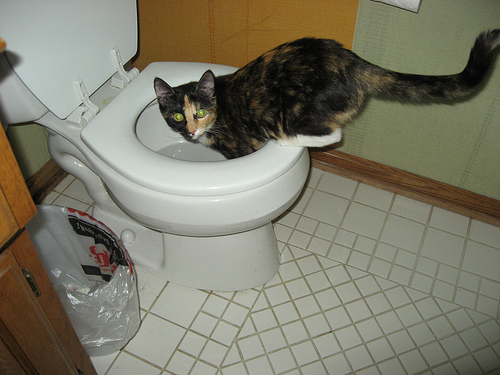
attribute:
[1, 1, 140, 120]
seat cover — toilet , white 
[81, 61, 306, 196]
seat — white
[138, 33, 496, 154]
cat — perched , calico , looking, black and brown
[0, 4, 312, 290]
toilet — white 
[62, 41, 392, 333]
toilet — white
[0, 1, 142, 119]
lid — open, white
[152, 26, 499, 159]
cat — black, tan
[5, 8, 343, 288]
toilet — porcelain , white 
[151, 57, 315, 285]
toilet — white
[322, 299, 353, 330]
tile — white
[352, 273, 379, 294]
tile — white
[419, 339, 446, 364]
tile — white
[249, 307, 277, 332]
tile — white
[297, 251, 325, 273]
tile — white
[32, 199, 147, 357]
trash can — small 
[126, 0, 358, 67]
wall — brown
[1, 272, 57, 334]
cabinet — wooden, brown